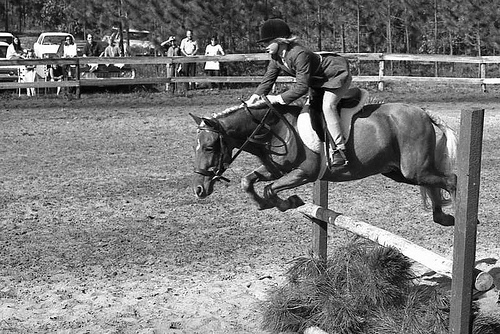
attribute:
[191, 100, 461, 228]
horse — brown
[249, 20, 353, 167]
rider — equestrian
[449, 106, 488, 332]
post — wooden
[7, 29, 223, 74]
people — watching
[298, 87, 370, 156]
saddle blanket — white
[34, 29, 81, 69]
car — parked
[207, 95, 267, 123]
mane — white